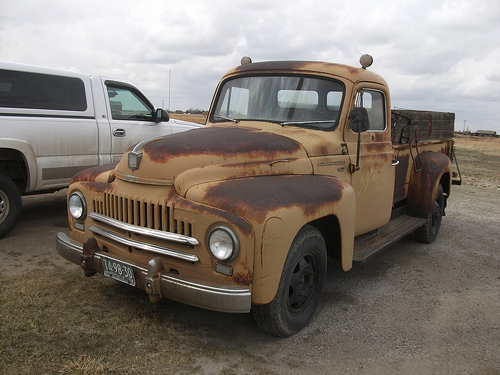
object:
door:
[341, 81, 395, 236]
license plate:
[101, 257, 136, 287]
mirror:
[349, 107, 369, 133]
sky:
[0, 0, 499, 134]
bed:
[389, 110, 456, 143]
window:
[1, 69, 91, 112]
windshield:
[213, 72, 344, 127]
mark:
[128, 125, 303, 163]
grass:
[4, 269, 218, 374]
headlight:
[206, 225, 241, 264]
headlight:
[65, 190, 87, 221]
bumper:
[54, 231, 252, 313]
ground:
[3, 159, 498, 370]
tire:
[251, 224, 329, 338]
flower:
[9, 301, 38, 319]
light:
[128, 152, 139, 169]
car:
[56, 54, 461, 339]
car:
[0, 61, 205, 238]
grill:
[92, 192, 193, 267]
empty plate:
[216, 170, 355, 222]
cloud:
[0, 0, 499, 122]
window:
[352, 88, 384, 131]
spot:
[203, 169, 343, 218]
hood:
[65, 125, 356, 305]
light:
[359, 54, 374, 68]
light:
[241, 56, 252, 66]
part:
[412, 147, 451, 220]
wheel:
[413, 183, 445, 243]